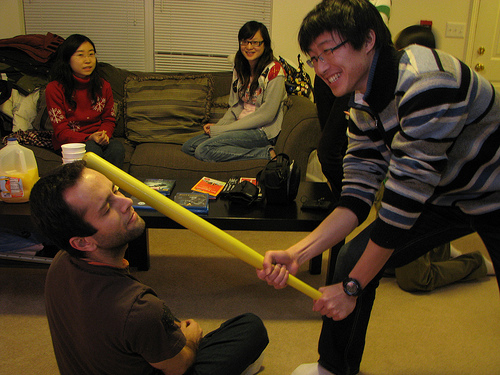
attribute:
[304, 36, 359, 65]
glasses — black 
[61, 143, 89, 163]
cups — white 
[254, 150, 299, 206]
bag — black 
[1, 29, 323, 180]
couch — dark 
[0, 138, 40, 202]
juice — orange 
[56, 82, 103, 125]
sweater — red 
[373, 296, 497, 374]
carpet — tan 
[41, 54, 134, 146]
sweater — grey, red 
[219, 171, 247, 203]
remote — black 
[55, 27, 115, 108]
hair — black 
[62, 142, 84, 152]
cup — white 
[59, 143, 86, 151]
cup — stacked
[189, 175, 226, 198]
manual — red , white , black 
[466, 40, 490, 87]
knobs — gold 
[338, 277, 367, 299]
watch — black 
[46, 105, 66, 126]
snowflake — white 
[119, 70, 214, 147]
pillow — green , brown 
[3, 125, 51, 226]
jug — Plastic 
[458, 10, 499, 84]
door — white 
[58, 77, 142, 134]
sweater — Red 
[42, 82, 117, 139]
snowflakes — white 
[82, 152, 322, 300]
bat — yellow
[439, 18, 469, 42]
switch plate — white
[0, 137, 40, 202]
jug — plastic 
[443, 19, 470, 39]
light switch — white 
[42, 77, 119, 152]
sweater — red , white 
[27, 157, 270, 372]
man — sitting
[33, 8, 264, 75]
blinds — white 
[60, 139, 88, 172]
cups — white 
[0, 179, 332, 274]
coffee table — black 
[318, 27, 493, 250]
shirt — black , blue , grey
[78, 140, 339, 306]
stick — yellow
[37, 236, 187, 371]
shirt — brown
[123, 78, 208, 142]
stripes — dark brown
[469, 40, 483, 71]
lock — gold